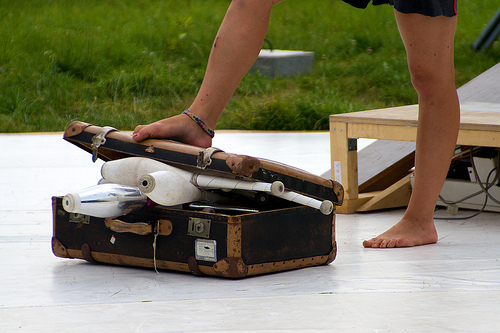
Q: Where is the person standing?
A: On a box.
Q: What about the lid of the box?
A: Lid is open.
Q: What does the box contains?
A: Juggling pins.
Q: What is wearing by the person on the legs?
A: An anklet.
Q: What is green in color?
A: The grass.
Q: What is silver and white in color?
A: Juggling pins.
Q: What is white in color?
A: Floor.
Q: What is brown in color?
A: The box.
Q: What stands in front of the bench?
A: The person.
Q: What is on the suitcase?
A: The person's foot.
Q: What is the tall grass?
A: Green.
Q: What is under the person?
A: The suitcase.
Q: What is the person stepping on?
A: A suitcase.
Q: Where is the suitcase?
A: ON the ground.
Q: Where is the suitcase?
A: Under a person.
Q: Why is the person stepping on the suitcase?
A: To close it.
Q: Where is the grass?
A: Behind the concrete.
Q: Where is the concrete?
A: Under the wooden platform.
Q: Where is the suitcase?
A: On the concrete.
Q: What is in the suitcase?
A: Bowling pins.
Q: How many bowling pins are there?
A: Three.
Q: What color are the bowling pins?
A: White.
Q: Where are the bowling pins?
A: Suitcase.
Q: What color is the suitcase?
A: Brown.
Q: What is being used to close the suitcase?
A: Foot.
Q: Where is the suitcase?
A: Ground.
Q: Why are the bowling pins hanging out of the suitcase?
A: Too long.